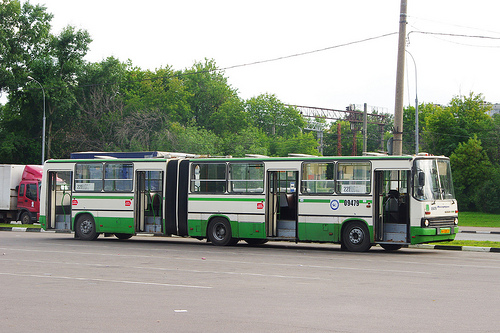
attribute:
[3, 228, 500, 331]
street — asphalt, large, gray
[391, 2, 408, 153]
utility pole — wooden, tall, brown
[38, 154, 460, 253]
bus — green, white, passenger bus, long, double length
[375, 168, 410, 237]
door — open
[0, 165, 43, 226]
truck — red, white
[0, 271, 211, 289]
line — white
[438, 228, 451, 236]
license plate — orange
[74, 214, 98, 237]
tire — black, rubber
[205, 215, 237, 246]
tire — black, rubber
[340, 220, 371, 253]
tire — black, rubber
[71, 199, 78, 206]
sticker — red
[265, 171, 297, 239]
door — open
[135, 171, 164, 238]
door — open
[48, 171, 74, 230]
door — open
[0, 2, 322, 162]
trees — green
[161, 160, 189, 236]
connector — black, rubber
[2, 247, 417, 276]
line — white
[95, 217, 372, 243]
bottom section — green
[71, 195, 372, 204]
stripe — green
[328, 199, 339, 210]
circle — blue